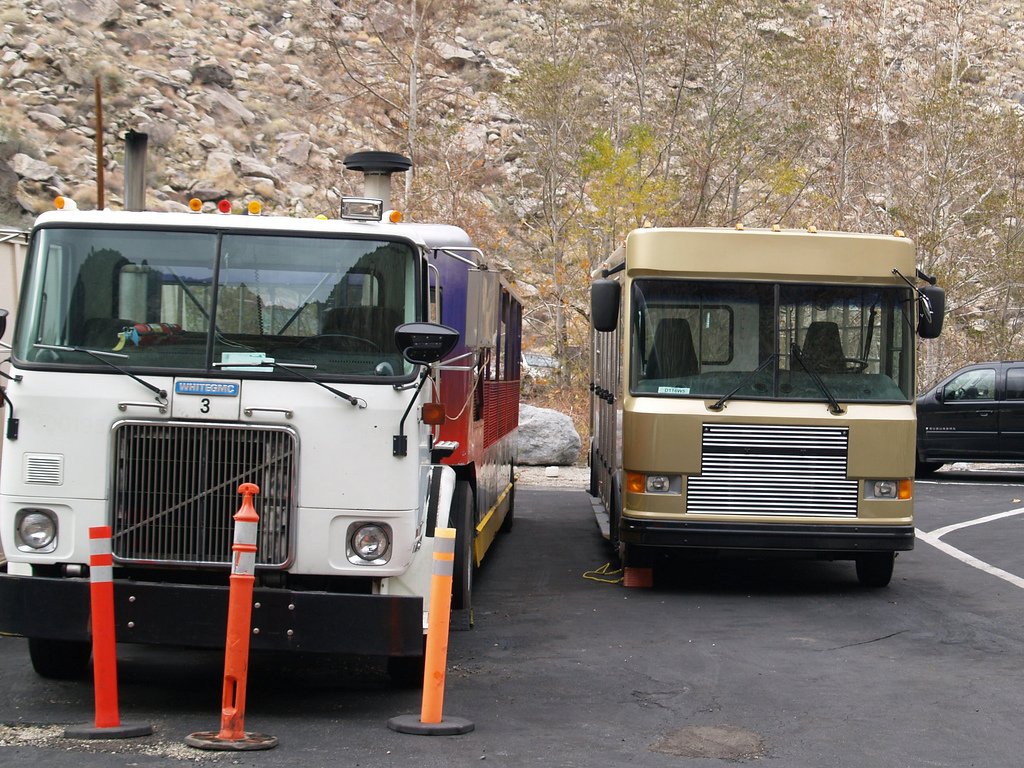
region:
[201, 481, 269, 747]
orange and white pylon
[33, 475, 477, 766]
a group of three pylons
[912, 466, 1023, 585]
white lines on the ground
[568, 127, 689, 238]
bright green leaves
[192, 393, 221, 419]
black number three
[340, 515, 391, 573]
circular light on the front of the truck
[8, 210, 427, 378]
large windshield on the front of the truck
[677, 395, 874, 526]
vent on the front of the truck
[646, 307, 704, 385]
front seat is empty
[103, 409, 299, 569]
vent on the front of the truck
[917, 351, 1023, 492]
SUV is dark colored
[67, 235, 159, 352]
reflection on the window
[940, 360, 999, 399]
window on the side of the vehicle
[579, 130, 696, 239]
light green leaves on the tree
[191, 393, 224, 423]
black number 3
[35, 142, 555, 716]
a white large truck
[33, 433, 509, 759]
a set of poles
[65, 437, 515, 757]
the poles are orange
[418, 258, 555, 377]
purple trim on truck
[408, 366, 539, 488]
red trim on the truck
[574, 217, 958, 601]
a tan bus on the side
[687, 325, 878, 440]
a pair of windshield wipers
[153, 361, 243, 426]
number on the truck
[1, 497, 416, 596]
lights on the truck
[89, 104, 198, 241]
vent on the truck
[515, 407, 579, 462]
a large boulder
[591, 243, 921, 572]
a brown motor home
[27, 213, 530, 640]
a large white truck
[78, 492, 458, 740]
orange traffic cones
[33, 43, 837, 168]
rocks on the hill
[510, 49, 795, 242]
a tree behind the motor home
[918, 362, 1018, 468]
a black truck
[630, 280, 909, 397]
the windshield on the motor home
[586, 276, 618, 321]
the side mirror on the motor home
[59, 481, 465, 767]
Poles are orange color.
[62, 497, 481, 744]
Poles are in road.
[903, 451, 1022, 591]
White lines in the road.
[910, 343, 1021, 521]
Car is black color.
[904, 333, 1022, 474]
Car is standing behind the bus.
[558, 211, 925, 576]
Bus is brown color.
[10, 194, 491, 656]
Truck is white color.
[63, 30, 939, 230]
Rocks are behind the vehicles.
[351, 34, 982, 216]
Trees are brown color.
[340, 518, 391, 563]
round head light on truck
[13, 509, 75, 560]
round head light on truck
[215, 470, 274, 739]
orange and white pole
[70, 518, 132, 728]
orange and white pole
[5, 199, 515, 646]
large white truck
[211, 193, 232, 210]
small red light on truck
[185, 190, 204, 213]
small orange light on truck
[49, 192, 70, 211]
small orange light on truck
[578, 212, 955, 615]
tan bus on the roadway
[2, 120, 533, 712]
white truck on the road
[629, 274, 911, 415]
front windshield of a tan bus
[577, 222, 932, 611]
Gold vehicle parked in lot.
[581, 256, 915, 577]
a large brown bus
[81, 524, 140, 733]
an orange traffic cone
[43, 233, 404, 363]
the windshield on the bus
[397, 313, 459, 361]
the mirror on the bus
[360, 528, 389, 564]
the headlight on the bus